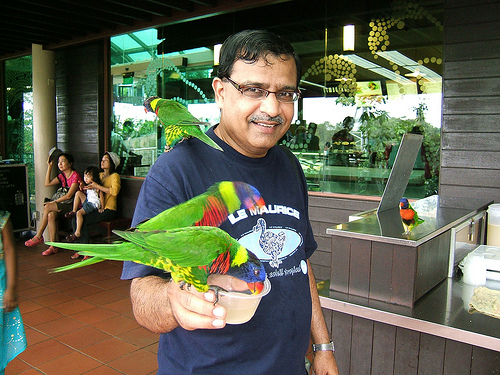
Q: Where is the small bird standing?
A: On the counter.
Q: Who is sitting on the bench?
A: A family.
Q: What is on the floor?
A: Red tiles.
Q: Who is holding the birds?
A: A man.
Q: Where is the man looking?
A: At the camera.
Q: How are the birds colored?
A: Green, red, and blue.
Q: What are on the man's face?
A: Glasses.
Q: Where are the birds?
A: On the man's hand.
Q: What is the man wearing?
A: A blue shirt.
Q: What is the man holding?
A: Birds.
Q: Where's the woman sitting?
A: On bench.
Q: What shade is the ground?
A: Brown.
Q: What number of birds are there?
A: 2.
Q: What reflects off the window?
A: City street.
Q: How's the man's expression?
A: Smiling.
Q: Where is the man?
A: In a shop.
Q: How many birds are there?
A: Three.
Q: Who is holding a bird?
A: A man with glasses.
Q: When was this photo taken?
A: During the day.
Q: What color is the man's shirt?
A: Blue.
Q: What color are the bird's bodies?
A: Green.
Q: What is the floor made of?
A: Tile.